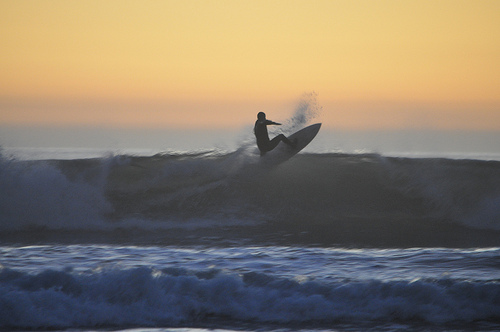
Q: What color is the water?
A: Blue.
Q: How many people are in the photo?
A: 1.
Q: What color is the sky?
A: Orange.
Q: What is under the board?
A: A wave.